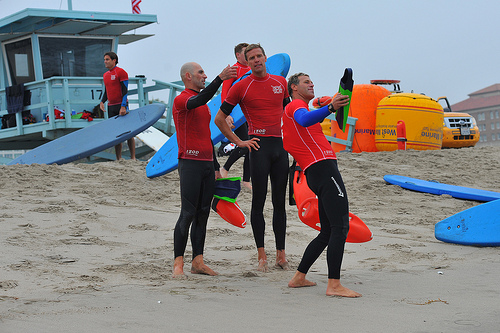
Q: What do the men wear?
A: Red tops.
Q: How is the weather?
A: Clear.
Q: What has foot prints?
A: The sand.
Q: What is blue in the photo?
A: The surfboard.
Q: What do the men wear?
A: Wetsuits.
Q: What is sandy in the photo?
A: The beach.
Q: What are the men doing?
A: Going surfing.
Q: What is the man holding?
A: A shoe.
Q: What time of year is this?
A: Summer.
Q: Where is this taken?
A: The beach.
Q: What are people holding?
A: Blue surfboards and orange life buoys.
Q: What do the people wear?
A: Wetsuits.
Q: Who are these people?
A: Lifeguards and or surfers.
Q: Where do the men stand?
A: On sand on the beach.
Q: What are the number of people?
A: Five.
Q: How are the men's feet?
A: Barefoot.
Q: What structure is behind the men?
A: A lifeguard station.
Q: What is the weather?
A: Cloudy and gray. .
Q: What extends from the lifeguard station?
A: A wood ramp.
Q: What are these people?
A: Lifeguards.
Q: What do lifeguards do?
A: Save people?.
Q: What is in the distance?
A: Lifeguard tower.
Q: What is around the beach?
A: Surfboards.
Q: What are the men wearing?
A: Wetsuits.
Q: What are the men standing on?
A: Sand.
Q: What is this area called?
A: The beach.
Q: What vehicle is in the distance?
A: SUV.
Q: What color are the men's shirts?
A: Red.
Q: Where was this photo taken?
A: At a beach.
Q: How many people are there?
A: Five.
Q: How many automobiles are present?
A: One.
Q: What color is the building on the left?
A: Blue.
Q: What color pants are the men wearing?
A: Black.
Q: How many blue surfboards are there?
A: Four.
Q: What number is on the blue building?
A: 17.